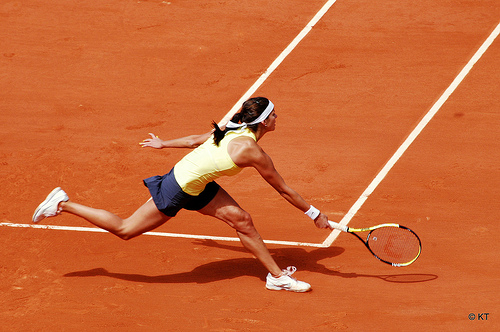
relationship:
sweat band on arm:
[302, 202, 322, 223] [237, 132, 333, 230]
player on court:
[29, 96, 335, 294] [292, 10, 493, 179]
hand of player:
[134, 130, 163, 151] [23, 88, 326, 298]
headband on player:
[228, 100, 275, 133] [26, 95, 422, 297]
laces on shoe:
[282, 263, 295, 274] [266, 270, 313, 292]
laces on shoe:
[282, 263, 295, 274] [30, 186, 67, 228]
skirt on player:
[146, 161, 226, 211] [23, 88, 326, 298]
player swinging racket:
[29, 96, 335, 294] [324, 212, 429, 269]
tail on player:
[200, 117, 245, 138] [29, 96, 335, 294]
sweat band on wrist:
[303, 204, 320, 220] [309, 209, 319, 224]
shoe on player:
[264, 266, 313, 293] [8, 51, 376, 301]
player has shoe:
[23, 88, 326, 298] [31, 186, 69, 223]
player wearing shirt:
[23, 88, 326, 298] [171, 124, 251, 190]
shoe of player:
[26, 183, 73, 225] [23, 88, 326, 298]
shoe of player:
[251, 261, 313, 293] [23, 88, 326, 298]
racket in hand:
[327, 220, 422, 268] [315, 211, 330, 230]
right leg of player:
[38, 189, 183, 233] [26, 95, 422, 297]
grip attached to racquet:
[326, 218, 350, 234] [317, 219, 430, 275]